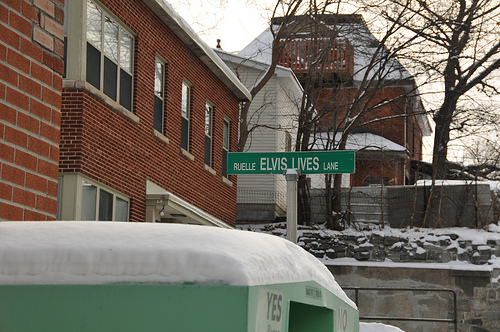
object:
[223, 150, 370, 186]
sign is green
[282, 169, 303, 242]
pole holds up sign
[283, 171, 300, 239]
there is a pole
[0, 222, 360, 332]
there is a structure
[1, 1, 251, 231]
there is a building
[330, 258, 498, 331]
slab is rock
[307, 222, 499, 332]
birm is rock slab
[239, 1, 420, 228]
there is a tree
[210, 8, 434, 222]
house is white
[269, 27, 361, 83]
there is a balcony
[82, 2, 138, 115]
there is a window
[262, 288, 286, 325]
letters are black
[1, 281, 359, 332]
black on green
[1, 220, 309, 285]
there is snow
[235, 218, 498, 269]
ground has snow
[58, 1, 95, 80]
building has siding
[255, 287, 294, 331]
there is a sign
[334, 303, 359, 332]
there is a no sign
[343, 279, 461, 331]
railing is metal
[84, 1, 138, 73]
window is reflecting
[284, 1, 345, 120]
branches lean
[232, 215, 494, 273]
snow covered wall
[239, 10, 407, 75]
roof has snow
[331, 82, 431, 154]
branches have snow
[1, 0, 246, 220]
three buildings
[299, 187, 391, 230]
snow on railing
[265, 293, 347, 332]
yes and no words.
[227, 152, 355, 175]
elvis sign.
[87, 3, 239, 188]
window rows.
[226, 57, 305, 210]
building in white.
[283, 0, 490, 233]
leafless trees.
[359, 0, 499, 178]
no leaves on trees.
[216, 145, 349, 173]
sign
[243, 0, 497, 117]
background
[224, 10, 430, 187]
house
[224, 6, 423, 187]
building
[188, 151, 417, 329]
street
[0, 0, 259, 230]
building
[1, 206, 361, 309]
snow